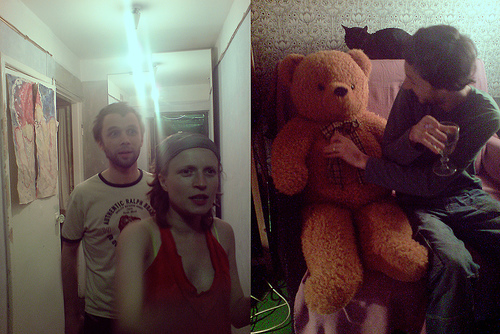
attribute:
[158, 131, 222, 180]
bandana — blue gray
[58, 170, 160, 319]
shirt — white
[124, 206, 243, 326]
shirt — red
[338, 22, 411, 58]
cat — black, small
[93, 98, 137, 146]
hair — short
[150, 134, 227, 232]
hair — grown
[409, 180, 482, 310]
pants — long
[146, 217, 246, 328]
tank top — red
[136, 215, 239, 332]
shirt — red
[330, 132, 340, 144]
ring — gold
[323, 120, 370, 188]
bowtie — plaid